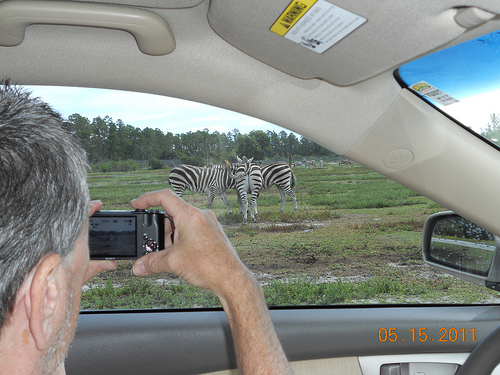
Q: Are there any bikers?
A: No, there are no bikers.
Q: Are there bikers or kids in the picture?
A: No, there are no bikers or kids.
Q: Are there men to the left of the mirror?
A: Yes, there is a man to the left of the mirror.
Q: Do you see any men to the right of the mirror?
A: No, the man is to the left of the mirror.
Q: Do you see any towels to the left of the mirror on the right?
A: No, there is a man to the left of the mirror.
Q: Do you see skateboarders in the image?
A: No, there are no skateboarders.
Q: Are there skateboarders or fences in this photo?
A: No, there are no skateboarders or fences.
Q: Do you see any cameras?
A: Yes, there is a camera.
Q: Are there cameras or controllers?
A: Yes, there is a camera.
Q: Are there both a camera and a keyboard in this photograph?
A: No, there is a camera but no keyboards.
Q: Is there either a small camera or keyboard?
A: Yes, there is a small camera.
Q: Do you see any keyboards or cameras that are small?
A: Yes, the camera is small.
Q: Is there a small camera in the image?
A: Yes, there is a small camera.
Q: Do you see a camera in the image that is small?
A: Yes, there is a camera that is small.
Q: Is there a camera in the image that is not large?
A: Yes, there is a small camera.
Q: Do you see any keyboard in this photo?
A: No, there are no keyboards.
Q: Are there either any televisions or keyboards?
A: No, there are no keyboards or televisions.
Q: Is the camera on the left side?
A: Yes, the camera is on the left of the image.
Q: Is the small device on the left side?
A: Yes, the camera is on the left of the image.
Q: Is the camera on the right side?
A: No, the camera is on the left of the image.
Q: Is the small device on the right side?
A: No, the camera is on the left of the image.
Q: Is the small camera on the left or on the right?
A: The camera is on the left of the image.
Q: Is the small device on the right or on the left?
A: The camera is on the left of the image.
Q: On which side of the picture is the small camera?
A: The camera is on the left of the image.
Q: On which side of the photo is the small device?
A: The camera is on the left of the image.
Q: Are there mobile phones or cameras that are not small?
A: No, there is a camera but it is small.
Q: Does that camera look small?
A: Yes, the camera is small.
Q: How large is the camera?
A: The camera is small.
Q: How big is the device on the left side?
A: The camera is small.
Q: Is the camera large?
A: No, the camera is small.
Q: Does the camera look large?
A: No, the camera is small.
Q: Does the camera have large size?
A: No, the camera is small.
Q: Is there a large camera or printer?
A: No, there is a camera but it is small.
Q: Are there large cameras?
A: No, there is a camera but it is small.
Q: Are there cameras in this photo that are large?
A: No, there is a camera but it is small.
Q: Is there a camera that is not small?
A: No, there is a camera but it is small.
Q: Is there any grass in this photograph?
A: Yes, there is grass.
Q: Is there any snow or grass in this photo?
A: Yes, there is grass.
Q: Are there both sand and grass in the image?
A: No, there is grass but no sand.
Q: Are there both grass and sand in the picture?
A: No, there is grass but no sand.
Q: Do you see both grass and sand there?
A: No, there is grass but no sand.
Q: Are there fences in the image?
A: No, there are no fences.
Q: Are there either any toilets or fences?
A: No, there are no fences or toilets.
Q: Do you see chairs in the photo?
A: No, there are no chairs.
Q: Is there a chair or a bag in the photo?
A: No, there are no chairs or bags.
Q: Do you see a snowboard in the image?
A: No, there are no snowboards.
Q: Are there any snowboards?
A: No, there are no snowboards.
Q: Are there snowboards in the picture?
A: No, there are no snowboards.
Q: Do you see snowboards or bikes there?
A: No, there are no snowboards or bikes.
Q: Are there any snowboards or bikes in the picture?
A: No, there are no snowboards or bikes.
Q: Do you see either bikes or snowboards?
A: No, there are no snowboards or bikes.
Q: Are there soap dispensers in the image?
A: No, there are no soap dispensers.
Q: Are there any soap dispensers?
A: No, there are no soap dispensers.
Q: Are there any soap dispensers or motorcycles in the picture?
A: No, there are no soap dispensers or motorcycles.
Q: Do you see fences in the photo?
A: No, there are no fences.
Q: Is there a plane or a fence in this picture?
A: No, there are no fences or airplanes.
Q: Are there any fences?
A: No, there are no fences.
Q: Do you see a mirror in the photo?
A: Yes, there is a mirror.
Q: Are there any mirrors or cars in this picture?
A: Yes, there is a mirror.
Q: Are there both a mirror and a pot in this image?
A: No, there is a mirror but no pots.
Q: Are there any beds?
A: No, there are no beds.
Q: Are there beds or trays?
A: No, there are no beds or trays.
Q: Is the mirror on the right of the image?
A: Yes, the mirror is on the right of the image.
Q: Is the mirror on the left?
A: No, the mirror is on the right of the image.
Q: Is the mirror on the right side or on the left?
A: The mirror is on the right of the image.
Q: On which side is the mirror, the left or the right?
A: The mirror is on the right of the image.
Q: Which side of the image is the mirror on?
A: The mirror is on the right of the image.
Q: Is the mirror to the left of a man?
A: No, the mirror is to the right of a man.